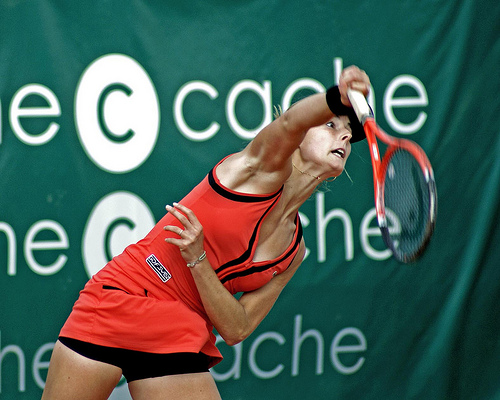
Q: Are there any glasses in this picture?
A: No, there are no glasses.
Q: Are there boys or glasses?
A: No, there are no glasses or boys.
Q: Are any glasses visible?
A: No, there are no glasses.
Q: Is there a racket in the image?
A: Yes, there is a racket.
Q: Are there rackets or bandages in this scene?
A: Yes, there is a racket.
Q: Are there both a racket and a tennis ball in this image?
A: No, there is a racket but no tennis balls.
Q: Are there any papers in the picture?
A: No, there are no papers.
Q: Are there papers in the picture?
A: No, there are no papers.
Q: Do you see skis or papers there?
A: No, there are no papers or skis.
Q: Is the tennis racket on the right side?
A: Yes, the tennis racket is on the right of the image.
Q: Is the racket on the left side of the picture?
A: No, the racket is on the right of the image.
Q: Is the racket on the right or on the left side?
A: The racket is on the right of the image.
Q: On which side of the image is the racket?
A: The racket is on the right of the image.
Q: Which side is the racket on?
A: The racket is on the right of the image.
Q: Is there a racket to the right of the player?
A: Yes, there is a racket to the right of the player.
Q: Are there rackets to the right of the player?
A: Yes, there is a racket to the right of the player.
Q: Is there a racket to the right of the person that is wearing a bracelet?
A: Yes, there is a racket to the right of the player.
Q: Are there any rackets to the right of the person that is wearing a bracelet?
A: Yes, there is a racket to the right of the player.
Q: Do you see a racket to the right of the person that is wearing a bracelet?
A: Yes, there is a racket to the right of the player.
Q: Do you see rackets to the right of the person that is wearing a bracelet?
A: Yes, there is a racket to the right of the player.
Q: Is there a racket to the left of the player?
A: No, the racket is to the right of the player.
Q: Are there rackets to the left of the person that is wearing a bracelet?
A: No, the racket is to the right of the player.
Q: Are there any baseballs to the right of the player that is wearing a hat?
A: No, there is a racket to the right of the player.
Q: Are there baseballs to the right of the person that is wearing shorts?
A: No, there is a racket to the right of the player.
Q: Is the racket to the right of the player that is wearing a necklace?
A: Yes, the racket is to the right of the player.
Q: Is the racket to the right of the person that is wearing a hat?
A: Yes, the racket is to the right of the player.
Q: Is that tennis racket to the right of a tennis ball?
A: No, the tennis racket is to the right of the player.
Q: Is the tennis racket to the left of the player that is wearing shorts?
A: No, the tennis racket is to the right of the player.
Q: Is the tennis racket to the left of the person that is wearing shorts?
A: No, the tennis racket is to the right of the player.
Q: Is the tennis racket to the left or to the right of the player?
A: The tennis racket is to the right of the player.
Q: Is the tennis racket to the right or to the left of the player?
A: The tennis racket is to the right of the player.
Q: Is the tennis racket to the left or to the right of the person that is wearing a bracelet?
A: The tennis racket is to the right of the player.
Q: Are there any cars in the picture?
A: No, there are no cars.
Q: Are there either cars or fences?
A: No, there are no cars or fences.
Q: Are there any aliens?
A: No, there are no aliens.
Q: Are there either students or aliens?
A: No, there are no aliens or students.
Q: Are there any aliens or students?
A: No, there are no aliens or students.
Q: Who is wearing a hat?
A: The player is wearing a hat.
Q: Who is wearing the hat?
A: The player is wearing a hat.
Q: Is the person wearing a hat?
A: Yes, the player is wearing a hat.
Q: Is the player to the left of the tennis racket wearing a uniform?
A: No, the player is wearing a hat.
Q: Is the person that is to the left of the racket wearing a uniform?
A: No, the player is wearing a hat.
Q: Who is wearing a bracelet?
A: The player is wearing a bracelet.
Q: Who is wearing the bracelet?
A: The player is wearing a bracelet.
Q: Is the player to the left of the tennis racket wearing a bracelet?
A: Yes, the player is wearing a bracelet.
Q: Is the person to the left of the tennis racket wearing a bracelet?
A: Yes, the player is wearing a bracelet.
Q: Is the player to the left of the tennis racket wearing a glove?
A: No, the player is wearing a bracelet.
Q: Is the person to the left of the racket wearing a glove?
A: No, the player is wearing a bracelet.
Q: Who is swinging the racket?
A: The player is swinging the racket.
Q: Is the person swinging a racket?
A: Yes, the player is swinging a racket.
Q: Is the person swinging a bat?
A: No, the player is swinging a racket.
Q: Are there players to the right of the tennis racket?
A: No, the player is to the left of the tennis racket.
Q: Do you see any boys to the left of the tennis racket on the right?
A: No, there is a player to the left of the tennis racket.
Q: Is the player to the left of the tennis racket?
A: Yes, the player is to the left of the tennis racket.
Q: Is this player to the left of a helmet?
A: No, the player is to the left of the tennis racket.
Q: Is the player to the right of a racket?
A: No, the player is to the left of a racket.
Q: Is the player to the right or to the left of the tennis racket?
A: The player is to the left of the tennis racket.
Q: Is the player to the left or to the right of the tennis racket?
A: The player is to the left of the tennis racket.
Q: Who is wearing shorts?
A: The player is wearing shorts.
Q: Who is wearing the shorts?
A: The player is wearing shorts.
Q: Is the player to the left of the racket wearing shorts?
A: Yes, the player is wearing shorts.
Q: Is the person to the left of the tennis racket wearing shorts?
A: Yes, the player is wearing shorts.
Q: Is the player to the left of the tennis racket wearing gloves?
A: No, the player is wearing shorts.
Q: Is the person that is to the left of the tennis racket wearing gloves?
A: No, the player is wearing shorts.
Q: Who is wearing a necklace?
A: The player is wearing a necklace.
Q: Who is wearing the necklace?
A: The player is wearing a necklace.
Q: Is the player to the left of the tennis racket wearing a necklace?
A: Yes, the player is wearing a necklace.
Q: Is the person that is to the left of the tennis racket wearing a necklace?
A: Yes, the player is wearing a necklace.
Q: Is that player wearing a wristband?
A: No, the player is wearing a necklace.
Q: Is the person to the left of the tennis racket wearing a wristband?
A: No, the player is wearing a necklace.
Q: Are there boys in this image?
A: No, there are no boys.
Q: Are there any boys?
A: No, there are no boys.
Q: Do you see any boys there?
A: No, there are no boys.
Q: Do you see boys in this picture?
A: No, there are no boys.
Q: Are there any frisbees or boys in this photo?
A: No, there are no boys or frisbees.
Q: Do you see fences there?
A: No, there are no fences.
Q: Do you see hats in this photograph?
A: Yes, there is a hat.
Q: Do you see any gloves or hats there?
A: Yes, there is a hat.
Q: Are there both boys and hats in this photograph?
A: No, there is a hat but no boys.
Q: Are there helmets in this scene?
A: No, there are no helmets.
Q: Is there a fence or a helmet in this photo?
A: No, there are no helmets or fences.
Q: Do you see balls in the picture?
A: No, there are no balls.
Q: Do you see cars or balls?
A: No, there are no balls or cars.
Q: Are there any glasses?
A: No, there are no glasses.